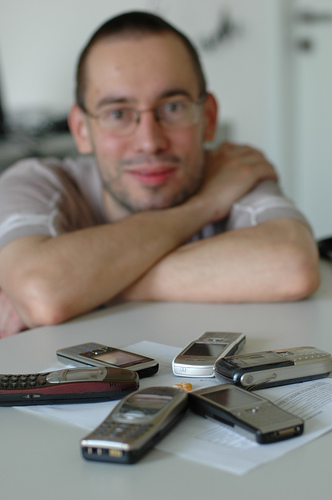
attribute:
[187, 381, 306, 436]
phone — is silver, is black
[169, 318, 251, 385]
cellphone — is silver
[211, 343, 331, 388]
flipphone — is cordless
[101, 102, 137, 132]
eye — on person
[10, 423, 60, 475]
table — is white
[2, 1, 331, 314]
man — is resting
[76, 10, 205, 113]
hair — on person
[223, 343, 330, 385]
set — is mobile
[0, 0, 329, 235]
background — is blurry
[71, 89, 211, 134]
eye lasses — pair 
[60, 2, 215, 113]
hair — on person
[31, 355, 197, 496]
cell phone — on wall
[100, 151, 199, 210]
beard — on wall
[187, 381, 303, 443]
hand set — is mobile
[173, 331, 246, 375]
phone —  candy bar style 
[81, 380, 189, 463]
cell phone — is black, is silver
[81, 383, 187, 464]
handset — is mobile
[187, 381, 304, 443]
handset — is mobile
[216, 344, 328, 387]
handset — is mobile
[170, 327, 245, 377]
handset — is mobile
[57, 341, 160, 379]
handset — is mobile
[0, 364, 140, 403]
handset — is mobile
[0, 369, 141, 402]
handset — is mobile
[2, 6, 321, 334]
man — on person